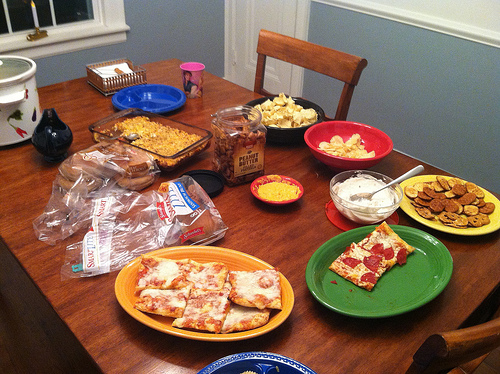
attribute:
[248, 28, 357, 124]
chair — wooden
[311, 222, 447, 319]
plate — green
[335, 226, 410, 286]
pizza — square, piled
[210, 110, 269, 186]
container — opened, plastic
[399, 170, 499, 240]
plate — yellow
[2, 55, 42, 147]
rice cooker — white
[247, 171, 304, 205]
bowl — small, red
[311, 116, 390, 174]
bowl — red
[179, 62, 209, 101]
cup — pink, small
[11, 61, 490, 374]
table — large, wooden, wood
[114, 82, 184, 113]
plate — blue, plastic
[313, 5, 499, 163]
wall — blue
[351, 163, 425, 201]
spoon — silver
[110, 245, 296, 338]
plate — orange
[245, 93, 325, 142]
bowl — black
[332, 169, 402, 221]
bowl — clear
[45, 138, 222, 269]
bags — plastic